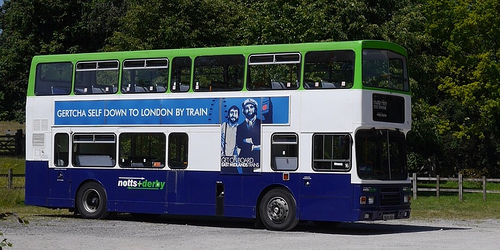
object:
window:
[373, 92, 405, 123]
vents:
[33, 139, 43, 140]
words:
[138, 179, 166, 189]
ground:
[42, 225, 138, 250]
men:
[222, 105, 239, 172]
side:
[28, 47, 363, 219]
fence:
[407, 173, 497, 200]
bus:
[23, 38, 416, 231]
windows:
[168, 55, 193, 94]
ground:
[446, 210, 479, 223]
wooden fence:
[457, 174, 464, 202]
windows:
[245, 55, 302, 90]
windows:
[54, 132, 70, 167]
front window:
[356, 128, 407, 180]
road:
[5, 217, 499, 247]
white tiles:
[184, 126, 223, 172]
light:
[369, 197, 373, 204]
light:
[364, 187, 370, 191]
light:
[404, 196, 408, 203]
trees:
[419, 49, 494, 176]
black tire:
[258, 188, 300, 230]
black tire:
[74, 181, 107, 219]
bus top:
[27, 40, 415, 95]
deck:
[25, 39, 404, 63]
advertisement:
[52, 95, 289, 174]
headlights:
[359, 196, 366, 205]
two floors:
[29, 55, 347, 173]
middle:
[22, 94, 411, 170]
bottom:
[21, 168, 367, 229]